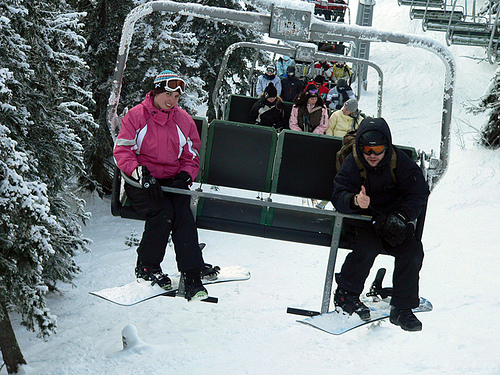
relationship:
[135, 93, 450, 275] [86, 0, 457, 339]
seats on ski lift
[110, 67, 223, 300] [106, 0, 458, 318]
lady are on chairlift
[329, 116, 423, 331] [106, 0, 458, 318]
people are on chairlift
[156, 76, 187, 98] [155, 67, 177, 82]
goggles are on hat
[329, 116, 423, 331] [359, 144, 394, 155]
people wearing goggles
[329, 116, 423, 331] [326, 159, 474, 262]
people wearing coat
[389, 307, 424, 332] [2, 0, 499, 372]
boot on snow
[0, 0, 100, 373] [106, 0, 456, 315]
tree next to ski lift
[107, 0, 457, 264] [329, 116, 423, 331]
ski lift carrying people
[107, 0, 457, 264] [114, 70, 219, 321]
ski lift carrying person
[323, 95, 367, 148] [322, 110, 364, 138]
lady wearing jacket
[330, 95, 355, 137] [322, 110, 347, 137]
lady with jacket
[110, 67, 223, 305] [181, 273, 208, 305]
lady with black/green shoes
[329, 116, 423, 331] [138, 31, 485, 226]
people on chairlift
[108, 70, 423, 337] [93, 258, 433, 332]
people wearing snowboards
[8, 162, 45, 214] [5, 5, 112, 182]
snow on trees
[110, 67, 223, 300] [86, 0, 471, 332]
lady riding a ski lift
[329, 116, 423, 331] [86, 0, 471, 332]
people riding a ski lift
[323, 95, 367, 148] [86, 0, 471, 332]
lady riding a ski lift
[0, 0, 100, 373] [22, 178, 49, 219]
tree with snow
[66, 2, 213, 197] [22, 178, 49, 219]
tree with snow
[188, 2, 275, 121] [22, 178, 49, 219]
tree with snow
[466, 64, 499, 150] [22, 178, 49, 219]
tree with snow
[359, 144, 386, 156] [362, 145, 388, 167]
goggles on persons face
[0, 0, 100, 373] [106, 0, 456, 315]
tree near ski lift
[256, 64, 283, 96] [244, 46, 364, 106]
person on a chairlift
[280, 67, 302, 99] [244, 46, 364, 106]
person on a chairlift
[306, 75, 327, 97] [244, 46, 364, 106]
person on a chairlift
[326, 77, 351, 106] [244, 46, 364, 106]
person on a chairlift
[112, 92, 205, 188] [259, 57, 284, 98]
coat on a woman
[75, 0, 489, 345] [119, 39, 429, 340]
lift carrying people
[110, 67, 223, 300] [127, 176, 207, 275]
lady wears pants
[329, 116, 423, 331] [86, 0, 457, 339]
people on ski lift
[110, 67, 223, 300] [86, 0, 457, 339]
lady on ski lift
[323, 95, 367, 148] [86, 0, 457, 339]
lady on ski lift